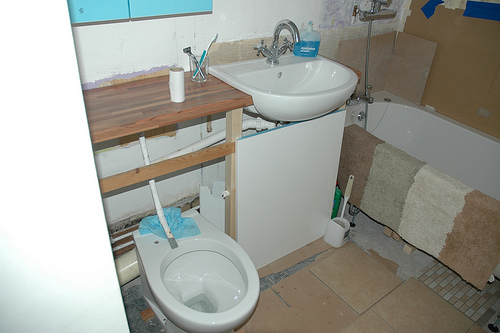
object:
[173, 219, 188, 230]
blue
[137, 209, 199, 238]
tissue paper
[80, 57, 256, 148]
shelf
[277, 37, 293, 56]
cold knob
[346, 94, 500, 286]
bathtub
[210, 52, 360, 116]
sink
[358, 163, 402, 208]
ground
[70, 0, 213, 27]
mirror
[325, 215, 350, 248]
holder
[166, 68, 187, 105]
paper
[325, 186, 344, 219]
toilet cleaner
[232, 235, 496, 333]
floor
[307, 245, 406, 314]
tiles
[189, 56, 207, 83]
cup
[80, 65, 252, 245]
table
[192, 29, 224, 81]
brush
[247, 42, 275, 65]
handle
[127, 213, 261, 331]
toilet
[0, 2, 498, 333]
bathroom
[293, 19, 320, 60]
soap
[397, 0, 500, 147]
cardboard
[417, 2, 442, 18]
tape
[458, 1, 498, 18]
tape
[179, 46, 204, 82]
razor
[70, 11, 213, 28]
bottom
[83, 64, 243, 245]
stand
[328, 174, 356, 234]
brush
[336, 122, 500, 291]
rug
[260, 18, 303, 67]
faucet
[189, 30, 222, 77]
tooth brush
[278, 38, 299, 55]
handle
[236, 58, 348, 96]
circle